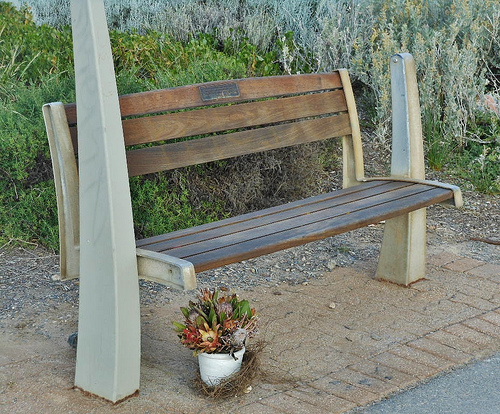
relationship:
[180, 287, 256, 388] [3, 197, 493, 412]
plant on ground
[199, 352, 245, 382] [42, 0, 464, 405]
flower pot by bench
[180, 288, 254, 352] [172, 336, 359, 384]
flower in pot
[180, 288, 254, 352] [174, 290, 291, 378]
flower has leaves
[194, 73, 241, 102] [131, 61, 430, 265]
plaque on bench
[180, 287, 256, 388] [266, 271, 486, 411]
plant on ground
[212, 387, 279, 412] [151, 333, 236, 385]
twigs underneath pot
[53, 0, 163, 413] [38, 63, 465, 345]
pole next to bench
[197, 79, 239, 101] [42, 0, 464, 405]
plaque on bench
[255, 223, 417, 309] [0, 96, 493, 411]
rocks on ground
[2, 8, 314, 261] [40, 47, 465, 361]
bush behind bench